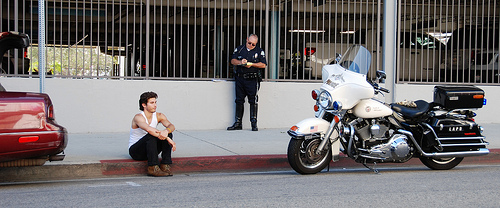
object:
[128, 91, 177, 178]
man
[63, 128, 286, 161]
sidewalk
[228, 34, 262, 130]
officer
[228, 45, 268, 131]
uniform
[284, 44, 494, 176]
motorcycle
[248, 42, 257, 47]
sunglasses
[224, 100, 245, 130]
boots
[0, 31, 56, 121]
trunk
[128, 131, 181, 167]
pants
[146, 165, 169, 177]
shoes